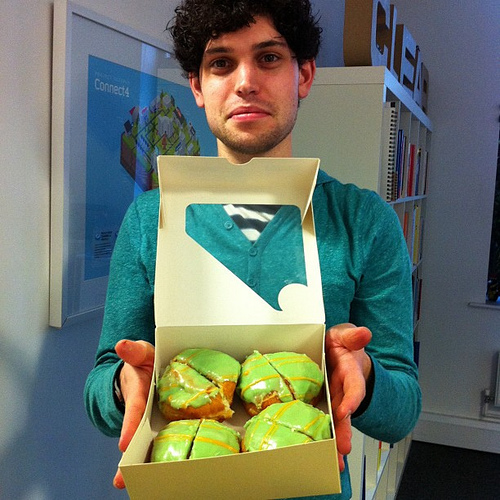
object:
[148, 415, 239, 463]
donunt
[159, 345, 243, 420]
donunt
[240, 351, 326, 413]
donunt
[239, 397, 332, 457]
donunt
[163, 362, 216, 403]
frosting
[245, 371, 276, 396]
frosting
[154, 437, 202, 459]
frosting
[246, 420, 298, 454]
frosting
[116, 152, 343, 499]
box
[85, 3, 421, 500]
man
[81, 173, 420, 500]
henley shirt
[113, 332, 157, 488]
hand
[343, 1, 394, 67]
letter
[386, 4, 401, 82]
letter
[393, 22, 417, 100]
letter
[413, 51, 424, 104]
letter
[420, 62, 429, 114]
letter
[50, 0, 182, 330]
picture frame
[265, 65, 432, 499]
bookshelf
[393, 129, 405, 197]
book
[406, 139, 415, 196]
book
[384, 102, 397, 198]
book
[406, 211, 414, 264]
book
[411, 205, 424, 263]
book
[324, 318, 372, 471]
hand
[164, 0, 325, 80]
hair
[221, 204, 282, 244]
shirt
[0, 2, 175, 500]
wall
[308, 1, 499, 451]
wall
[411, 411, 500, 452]
moulding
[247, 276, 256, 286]
button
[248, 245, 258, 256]
button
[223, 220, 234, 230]
button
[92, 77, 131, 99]
connect4 word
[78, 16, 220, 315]
picture